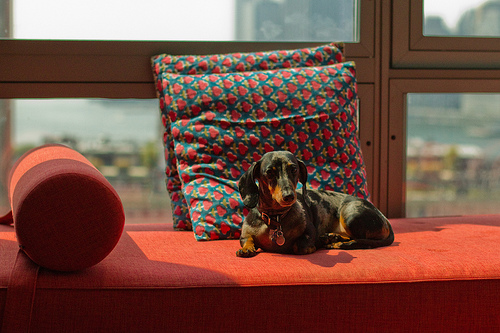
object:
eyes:
[266, 169, 275, 177]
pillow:
[149, 40, 345, 231]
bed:
[1, 212, 498, 329]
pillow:
[6, 143, 125, 273]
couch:
[0, 210, 497, 333]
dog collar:
[256, 196, 298, 246]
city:
[0, 126, 498, 221]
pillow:
[157, 61, 374, 247]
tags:
[268, 225, 284, 245]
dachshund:
[234, 150, 394, 260]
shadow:
[283, 248, 353, 270]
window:
[3, 2, 499, 220]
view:
[68, 117, 473, 187]